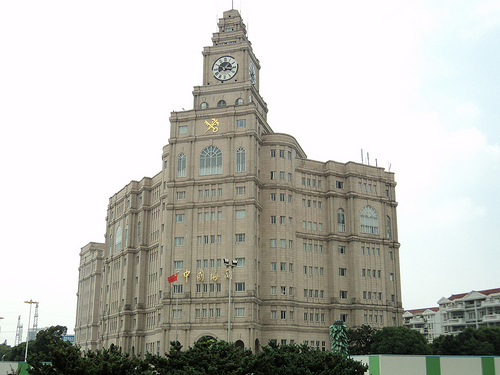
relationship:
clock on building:
[211, 57, 238, 81] [60, 3, 406, 363]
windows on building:
[195, 145, 222, 176] [60, 3, 406, 363]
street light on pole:
[223, 257, 239, 270] [229, 264, 231, 375]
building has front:
[60, 3, 406, 363] [162, 44, 256, 358]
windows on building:
[174, 145, 246, 177] [60, 3, 406, 363]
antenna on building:
[232, 1, 234, 11] [60, 3, 406, 363]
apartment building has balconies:
[401, 287, 499, 345] [446, 315, 499, 325]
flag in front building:
[168, 272, 180, 284] [60, 3, 406, 363]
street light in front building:
[223, 257, 239, 270] [43, 10, 455, 373]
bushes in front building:
[6, 326, 493, 373] [60, 3, 406, 363]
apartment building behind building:
[401, 287, 499, 345] [60, 3, 406, 363]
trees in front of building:
[2, 323, 395, 373] [60, 3, 406, 363]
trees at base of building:
[147, 334, 264, 375] [60, 3, 406, 363]